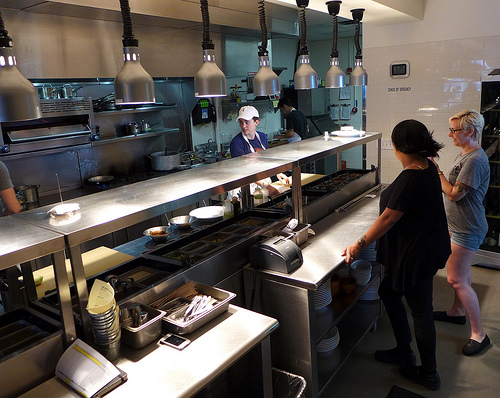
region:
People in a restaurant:
[335, 106, 499, 392]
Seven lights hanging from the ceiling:
[0, 4, 392, 121]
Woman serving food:
[216, 99, 296, 204]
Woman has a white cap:
[223, 96, 289, 209]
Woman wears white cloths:
[338, 112, 460, 394]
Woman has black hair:
[341, 100, 463, 396]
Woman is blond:
[431, 93, 498, 364]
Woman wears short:
[431, 102, 498, 377]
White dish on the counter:
[188, 196, 230, 223]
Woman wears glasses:
[437, 104, 499, 367]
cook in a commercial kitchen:
[219, 96, 278, 160]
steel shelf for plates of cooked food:
[112, 121, 384, 218]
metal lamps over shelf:
[0, 44, 371, 119]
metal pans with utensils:
[151, 269, 247, 336]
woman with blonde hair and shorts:
[442, 99, 497, 361]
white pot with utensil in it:
[141, 141, 188, 173]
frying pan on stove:
[74, 165, 127, 192]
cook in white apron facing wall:
[274, 94, 311, 150]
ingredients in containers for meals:
[178, 207, 278, 265]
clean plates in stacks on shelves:
[309, 263, 342, 358]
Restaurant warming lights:
[5, 46, 377, 108]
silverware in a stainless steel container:
[168, 272, 225, 349]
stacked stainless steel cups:
[83, 291, 115, 368]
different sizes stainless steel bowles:
[109, 193, 229, 250]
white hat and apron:
[224, 107, 277, 162]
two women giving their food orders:
[366, 101, 491, 380]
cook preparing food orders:
[267, 101, 308, 146]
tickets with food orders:
[29, 174, 77, 244]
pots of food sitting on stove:
[76, 137, 188, 190]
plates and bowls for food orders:
[311, 257, 376, 357]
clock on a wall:
[383, 54, 420, 84]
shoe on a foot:
[453, 323, 497, 365]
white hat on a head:
[231, 100, 263, 131]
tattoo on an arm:
[353, 231, 374, 254]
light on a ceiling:
[345, 4, 374, 97]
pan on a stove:
[81, 162, 124, 194]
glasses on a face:
[440, 118, 474, 140]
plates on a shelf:
[303, 273, 348, 318]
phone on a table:
[155, 324, 195, 360]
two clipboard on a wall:
[326, 100, 355, 123]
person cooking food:
[197, 85, 332, 270]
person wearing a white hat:
[221, 93, 294, 229]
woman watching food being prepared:
[368, 93, 497, 379]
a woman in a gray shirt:
[435, 95, 495, 336]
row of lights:
[6, 46, 418, 158]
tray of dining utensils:
[121, 273, 248, 325]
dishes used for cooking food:
[73, 153, 245, 239]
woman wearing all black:
[361, 111, 459, 389]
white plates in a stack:
[306, 270, 407, 357]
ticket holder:
[41, 161, 81, 225]